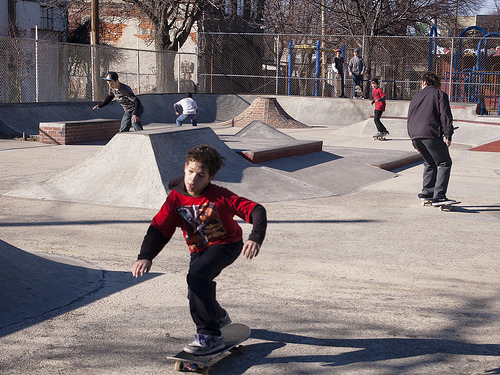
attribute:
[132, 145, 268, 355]
boy — young, small, skateboarding, skating, little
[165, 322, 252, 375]
skateboard — black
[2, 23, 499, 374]
park — for skating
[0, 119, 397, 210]
ramp — cement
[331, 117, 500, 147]
ramp — cement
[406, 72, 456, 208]
man — large, skateboarding, skating, playing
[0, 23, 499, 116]
fence — chain link, gray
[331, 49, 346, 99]
boy — watching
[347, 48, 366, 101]
boy — watching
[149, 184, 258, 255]
shirt — red, short sleeved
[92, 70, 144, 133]
person — skating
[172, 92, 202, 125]
person — skating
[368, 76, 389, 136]
person — skating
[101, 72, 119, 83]
hat — dark, black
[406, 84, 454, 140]
shirt — dark, black, long sleeved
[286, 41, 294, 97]
pole — blue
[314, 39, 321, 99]
pole — blue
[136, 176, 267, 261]
hoodie — dark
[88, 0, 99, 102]
pole — wooden, brown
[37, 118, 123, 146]
bench — brick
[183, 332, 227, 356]
shoe — gray, white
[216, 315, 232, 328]
shoe — gray, white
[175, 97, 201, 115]
t-shirt — white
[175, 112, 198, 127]
jeans — blue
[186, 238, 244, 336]
pants — black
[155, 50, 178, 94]
trunk — large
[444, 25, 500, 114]
equipment — blue